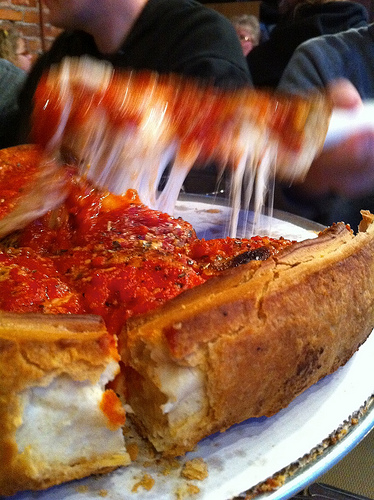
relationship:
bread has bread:
[1, 159, 360, 486] [0, 310, 137, 492]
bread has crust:
[1, 159, 360, 486] [206, 237, 372, 458]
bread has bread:
[91, 250, 344, 434] [0, 310, 137, 492]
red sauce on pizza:
[14, 85, 226, 305] [1, 58, 373, 498]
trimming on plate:
[124, 433, 249, 498] [1, 190, 372, 497]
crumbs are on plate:
[99, 442, 214, 497] [55, 193, 356, 470]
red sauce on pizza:
[0, 138, 295, 324] [1, 58, 373, 498]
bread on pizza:
[114, 208, 373, 461] [0, 59, 373, 498]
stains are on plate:
[206, 430, 255, 477] [125, 183, 372, 495]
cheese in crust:
[12, 354, 206, 467] [0, 205, 374, 496]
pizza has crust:
[1, 58, 373, 498] [0, 205, 374, 496]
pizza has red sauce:
[0, 59, 373, 498] [0, 138, 295, 324]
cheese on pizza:
[52, 57, 274, 234] [1, 58, 373, 498]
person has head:
[230, 12, 271, 87] [230, 16, 258, 56]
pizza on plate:
[0, 59, 373, 498] [1, 190, 372, 497]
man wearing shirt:
[17, 2, 257, 203] [14, 2, 254, 207]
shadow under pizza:
[193, 204, 267, 242] [4, 192, 350, 461]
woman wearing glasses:
[1, 20, 33, 70] [6, 46, 31, 57]